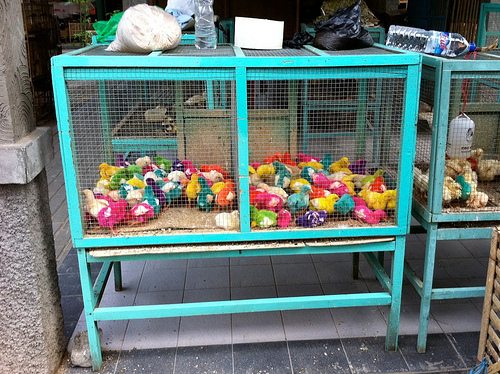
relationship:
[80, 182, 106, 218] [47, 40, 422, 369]
bird in cage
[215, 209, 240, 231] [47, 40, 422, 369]
bird in cage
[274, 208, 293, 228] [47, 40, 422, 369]
bird in cage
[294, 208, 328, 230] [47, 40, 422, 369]
bird in cage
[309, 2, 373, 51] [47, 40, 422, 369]
bag on top of cage